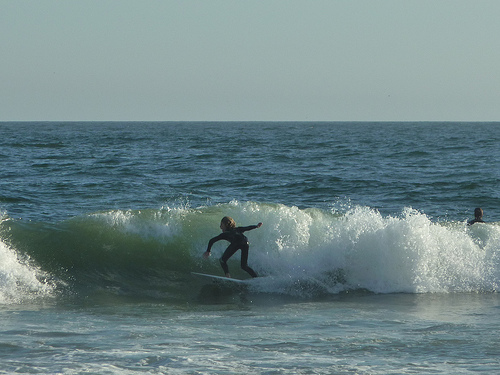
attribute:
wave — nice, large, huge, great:
[0, 208, 499, 301]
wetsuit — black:
[208, 224, 259, 278]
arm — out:
[239, 223, 265, 233]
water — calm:
[0, 307, 498, 375]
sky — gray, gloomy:
[3, 1, 500, 124]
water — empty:
[4, 120, 499, 203]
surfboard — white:
[197, 272, 246, 285]